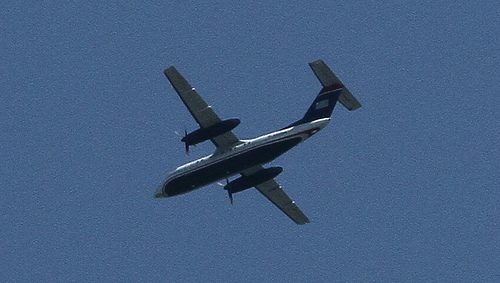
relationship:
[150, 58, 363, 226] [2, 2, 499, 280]
plane in blue sky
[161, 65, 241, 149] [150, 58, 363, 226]
left wing on plane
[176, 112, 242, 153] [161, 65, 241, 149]
engine on left wing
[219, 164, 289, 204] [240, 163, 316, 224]
engine on right wing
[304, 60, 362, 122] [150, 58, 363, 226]
verticle stabilizer on plane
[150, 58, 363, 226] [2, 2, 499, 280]
plane flying in blue sky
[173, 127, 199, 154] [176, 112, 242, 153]
propellor on engine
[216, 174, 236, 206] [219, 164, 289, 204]
propellor on engine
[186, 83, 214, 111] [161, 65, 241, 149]
horizonal stabilizer on left wing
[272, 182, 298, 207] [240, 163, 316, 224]
horizonal stabilizer on right wing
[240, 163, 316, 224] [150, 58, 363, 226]
right wing of plane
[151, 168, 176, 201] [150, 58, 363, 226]
nose of plane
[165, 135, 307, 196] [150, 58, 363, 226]
belly of plane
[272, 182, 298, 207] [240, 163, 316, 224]
elevator of right wing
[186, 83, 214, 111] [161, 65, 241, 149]
elevator of left wing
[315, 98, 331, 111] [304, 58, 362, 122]
small white square on verticle stabilizer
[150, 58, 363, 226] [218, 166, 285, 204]
plane has two engine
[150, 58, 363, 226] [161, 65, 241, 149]
plane has left wing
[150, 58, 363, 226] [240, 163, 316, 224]
plane has right wing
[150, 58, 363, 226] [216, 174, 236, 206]
plane has propellor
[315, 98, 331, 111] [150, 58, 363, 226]
us airways logo printed on plane